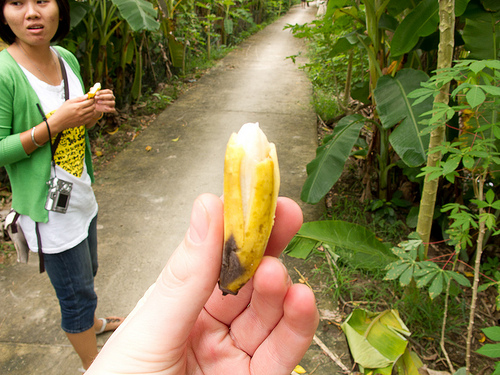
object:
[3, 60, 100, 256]
white shirt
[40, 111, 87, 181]
yellow heart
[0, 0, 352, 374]
path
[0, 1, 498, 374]
banana grove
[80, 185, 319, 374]
hand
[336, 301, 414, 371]
leaf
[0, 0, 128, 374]
woman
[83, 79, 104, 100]
banana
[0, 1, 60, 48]
head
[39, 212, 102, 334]
jeans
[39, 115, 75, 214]
digital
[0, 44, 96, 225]
cardigan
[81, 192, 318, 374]
person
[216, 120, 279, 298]
banana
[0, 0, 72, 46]
black hair